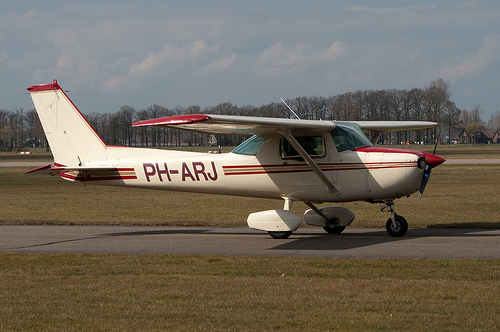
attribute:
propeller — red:
[406, 137, 450, 189]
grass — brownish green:
[10, 154, 497, 330]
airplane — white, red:
[23, 74, 446, 239]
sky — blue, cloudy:
[0, 5, 498, 150]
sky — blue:
[210, 1, 345, 19]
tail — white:
[18, 71, 146, 211]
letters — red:
[141, 154, 219, 197]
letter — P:
[135, 158, 159, 194]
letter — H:
[155, 159, 170, 179]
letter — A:
[179, 164, 193, 185]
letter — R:
[191, 155, 207, 182]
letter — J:
[210, 158, 223, 184]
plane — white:
[26, 35, 464, 269]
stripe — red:
[232, 159, 278, 178]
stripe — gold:
[100, 166, 142, 176]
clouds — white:
[126, 45, 240, 80]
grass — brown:
[175, 268, 265, 320]